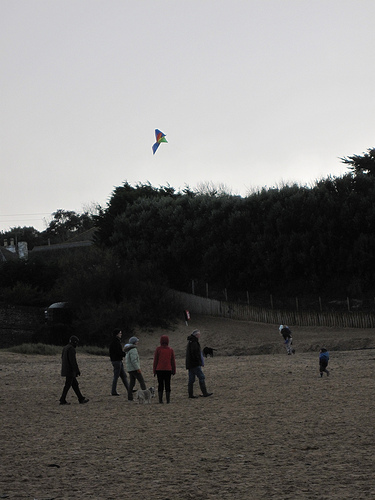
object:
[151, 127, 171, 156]
kite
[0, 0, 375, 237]
sky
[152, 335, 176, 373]
shirt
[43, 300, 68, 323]
building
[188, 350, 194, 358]
black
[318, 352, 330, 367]
jacket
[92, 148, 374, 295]
trees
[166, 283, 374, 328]
fence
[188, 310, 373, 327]
road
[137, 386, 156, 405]
dog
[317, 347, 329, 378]
boy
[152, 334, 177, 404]
girl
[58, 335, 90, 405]
man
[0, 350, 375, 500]
beach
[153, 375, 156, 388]
leash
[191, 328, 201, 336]
hat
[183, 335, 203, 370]
coat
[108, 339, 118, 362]
backpack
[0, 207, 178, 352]
hill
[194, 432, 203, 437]
footprints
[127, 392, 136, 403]
boots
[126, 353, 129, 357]
gloves